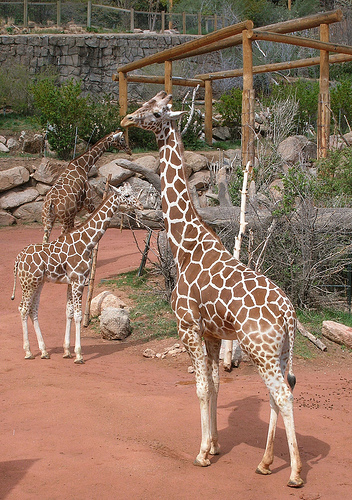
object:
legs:
[173, 325, 235, 473]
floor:
[2, 225, 350, 498]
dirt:
[0, 353, 351, 466]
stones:
[96, 307, 131, 344]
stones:
[84, 287, 107, 323]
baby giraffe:
[8, 176, 144, 373]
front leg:
[189, 323, 211, 465]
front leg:
[203, 331, 223, 458]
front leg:
[71, 282, 86, 365]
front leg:
[62, 283, 74, 359]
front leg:
[82, 198, 96, 214]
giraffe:
[9, 179, 144, 365]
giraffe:
[40, 125, 133, 242]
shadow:
[64, 328, 131, 362]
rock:
[99, 307, 132, 340]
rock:
[101, 293, 130, 311]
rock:
[87, 289, 110, 318]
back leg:
[255, 331, 291, 477]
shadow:
[213, 388, 335, 485]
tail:
[279, 297, 305, 393]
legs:
[254, 350, 303, 489]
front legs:
[170, 281, 222, 467]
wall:
[3, 30, 254, 106]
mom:
[113, 85, 324, 494]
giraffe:
[119, 89, 330, 493]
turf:
[287, 371, 296, 388]